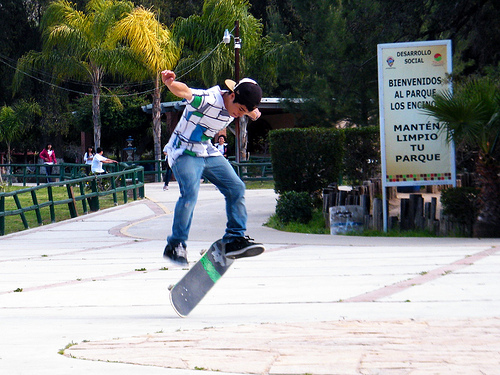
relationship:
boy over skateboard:
[157, 65, 264, 265] [169, 231, 245, 318]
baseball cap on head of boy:
[223, 76, 258, 108] [157, 65, 264, 265]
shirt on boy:
[107, 53, 342, 326] [126, 42, 287, 285]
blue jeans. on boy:
[167, 150, 244, 241] [157, 65, 264, 265]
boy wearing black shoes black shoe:
[157, 65, 264, 265] [220, 235, 265, 260]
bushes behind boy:
[268, 122, 378, 220] [144, 61, 270, 263]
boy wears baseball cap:
[157, 65, 264, 265] [223, 76, 258, 108]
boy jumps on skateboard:
[157, 65, 264, 265] [169, 238, 234, 317]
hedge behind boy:
[267, 124, 382, 194] [157, 65, 264, 265]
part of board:
[398, 56, 438, 116] [376, 36, 456, 231]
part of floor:
[327, 321, 375, 349] [1, 182, 497, 374]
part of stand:
[369, 160, 409, 233] [371, 177, 403, 229]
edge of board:
[165, 286, 194, 314] [159, 270, 206, 331]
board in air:
[166, 237, 242, 320] [120, 27, 328, 308]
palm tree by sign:
[437, 48, 490, 229] [368, 33, 464, 237]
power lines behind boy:
[3, 55, 215, 99] [157, 65, 264, 265]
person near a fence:
[82, 140, 117, 210] [0, 158, 150, 246]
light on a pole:
[219, 27, 233, 47] [219, 16, 251, 179]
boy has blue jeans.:
[157, 65, 264, 265] [167, 150, 244, 241]